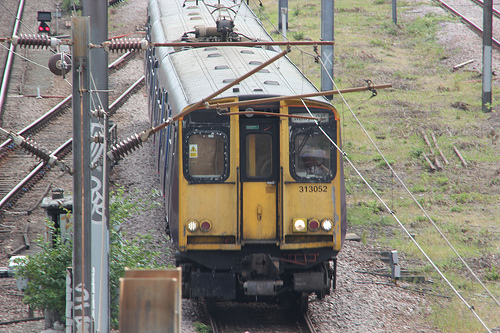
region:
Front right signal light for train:
[180, 216, 222, 233]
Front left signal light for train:
[283, 212, 334, 245]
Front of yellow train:
[170, 100, 353, 290]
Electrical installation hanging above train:
[93, 33, 418, 200]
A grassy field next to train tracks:
[368, 1, 497, 102]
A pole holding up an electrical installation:
[34, 11, 136, 331]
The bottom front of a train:
[178, 261, 311, 332]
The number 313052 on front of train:
[285, 173, 341, 193]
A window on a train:
[180, 127, 230, 181]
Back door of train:
[225, 92, 292, 263]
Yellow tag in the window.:
[183, 145, 211, 166]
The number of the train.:
[265, 175, 331, 206]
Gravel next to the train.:
[363, 288, 388, 314]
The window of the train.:
[193, 125, 233, 171]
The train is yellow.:
[226, 202, 269, 236]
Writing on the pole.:
[89, 127, 117, 176]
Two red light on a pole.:
[35, 17, 70, 42]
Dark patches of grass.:
[464, 177, 491, 198]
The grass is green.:
[426, 231, 457, 247]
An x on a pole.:
[320, 51, 333, 68]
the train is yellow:
[171, 94, 353, 269]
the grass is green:
[395, 64, 462, 169]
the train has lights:
[182, 210, 349, 250]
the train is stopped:
[133, 8, 365, 318]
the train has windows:
[180, 105, 355, 193]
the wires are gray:
[277, 36, 492, 299]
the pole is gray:
[68, 1, 126, 328]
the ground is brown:
[343, 280, 400, 323]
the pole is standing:
[314, 1, 351, 92]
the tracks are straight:
[197, 299, 354, 329]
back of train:
[179, 108, 350, 262]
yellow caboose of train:
[189, 114, 361, 284]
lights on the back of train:
[295, 217, 350, 241]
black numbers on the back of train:
[292, 184, 335, 202]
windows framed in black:
[181, 122, 234, 203]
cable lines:
[263, 27, 498, 263]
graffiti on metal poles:
[67, 70, 104, 254]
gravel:
[346, 251, 413, 329]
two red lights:
[24, 8, 65, 38]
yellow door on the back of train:
[236, 135, 289, 252]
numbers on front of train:
[297, 180, 332, 201]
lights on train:
[282, 213, 348, 238]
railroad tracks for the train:
[193, 289, 338, 331]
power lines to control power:
[49, 139, 131, 312]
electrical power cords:
[357, 110, 455, 305]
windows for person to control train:
[287, 129, 343, 214]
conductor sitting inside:
[300, 152, 336, 178]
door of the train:
[230, 112, 295, 258]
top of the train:
[145, 26, 317, 108]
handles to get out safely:
[230, 167, 251, 247]